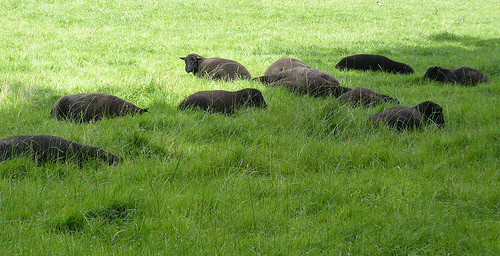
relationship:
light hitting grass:
[1, 0, 499, 100] [70, 16, 174, 79]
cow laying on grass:
[178, 85, 272, 121] [2, 1, 497, 50]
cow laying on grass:
[48, 85, 153, 125] [2, 1, 497, 50]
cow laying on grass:
[178, 45, 258, 84] [2, 1, 497, 50]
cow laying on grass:
[256, 51, 348, 101] [2, 1, 497, 50]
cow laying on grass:
[335, 81, 400, 108] [2, 1, 497, 50]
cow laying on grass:
[368, 97, 450, 138] [2, 1, 497, 50]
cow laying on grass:
[336, 53, 415, 83] [2, 1, 497, 50]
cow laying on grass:
[421, 59, 494, 91] [2, 1, 497, 50]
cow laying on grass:
[0, 130, 125, 179] [2, 1, 497, 50]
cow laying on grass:
[48, 85, 153, 125] [0, 3, 496, 253]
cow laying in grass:
[178, 85, 272, 121] [0, 3, 496, 253]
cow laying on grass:
[336, 53, 415, 83] [340, 64, 417, 98]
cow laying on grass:
[421, 59, 494, 91] [0, 3, 496, 253]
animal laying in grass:
[3, 131, 118, 167] [8, 157, 465, 252]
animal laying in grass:
[369, 100, 449, 136] [22, 10, 474, 236]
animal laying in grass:
[422, 63, 487, 85] [22, 10, 474, 236]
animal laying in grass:
[337, 48, 416, 77] [22, 10, 474, 236]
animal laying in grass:
[173, 85, 270, 117] [22, 10, 474, 236]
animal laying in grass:
[51, 92, 146, 122] [22, 10, 474, 236]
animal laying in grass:
[334, 82, 396, 107] [0, 3, 496, 253]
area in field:
[45, 192, 146, 240] [2, 1, 493, 254]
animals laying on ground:
[95, 47, 467, 171] [1, 1, 499, 251]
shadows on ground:
[375, 22, 499, 67] [1, 1, 499, 251]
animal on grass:
[173, 85, 270, 117] [194, 212, 289, 253]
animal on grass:
[258, 65, 350, 97] [0, 3, 496, 253]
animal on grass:
[258, 56, 350, 97] [0, 3, 496, 253]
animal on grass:
[51, 92, 146, 122] [115, 133, 452, 241]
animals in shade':
[0, 47, 499, 171] [1, 39, 488, 254]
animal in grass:
[369, 100, 428, 136] [0, 3, 496, 253]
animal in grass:
[258, 56, 350, 97] [255, 81, 365, 158]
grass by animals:
[305, 82, 374, 144] [0, 52, 491, 168]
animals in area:
[0, 47, 499, 171] [45, 192, 146, 240]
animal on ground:
[51, 92, 146, 122] [1, 1, 499, 251]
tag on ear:
[191, 47, 208, 64] [194, 49, 204, 66]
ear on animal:
[194, 49, 204, 66] [166, 43, 253, 83]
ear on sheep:
[177, 54, 189, 61] [176, 50, 254, 85]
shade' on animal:
[1, 39, 500, 254] [366, 103, 430, 133]